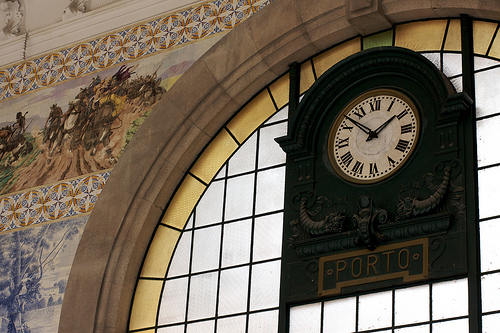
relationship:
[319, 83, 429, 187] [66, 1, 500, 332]
clock on window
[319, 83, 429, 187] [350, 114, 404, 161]
clock has face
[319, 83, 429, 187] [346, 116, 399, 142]
clock has hands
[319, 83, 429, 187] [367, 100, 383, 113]
clock has numerals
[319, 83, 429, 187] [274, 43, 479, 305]
clock in frame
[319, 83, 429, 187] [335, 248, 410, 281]
clock says writings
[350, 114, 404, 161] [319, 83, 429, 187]
face of clock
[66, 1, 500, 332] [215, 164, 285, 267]
window has tiles